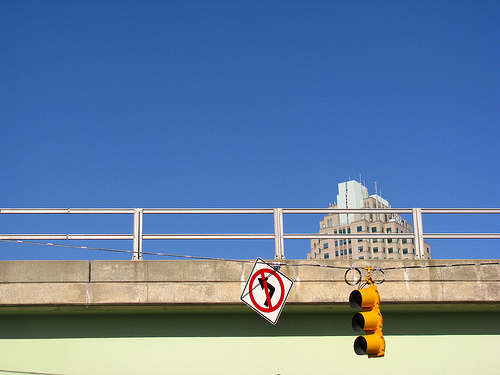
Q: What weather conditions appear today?
A: It is cloudless.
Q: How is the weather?
A: It is cloudless.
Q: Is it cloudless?
A: Yes, it is cloudless.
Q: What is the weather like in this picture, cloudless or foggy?
A: It is cloudless.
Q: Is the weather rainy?
A: No, it is cloudless.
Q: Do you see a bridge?
A: Yes, there is a bridge.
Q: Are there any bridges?
A: Yes, there is a bridge.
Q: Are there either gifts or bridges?
A: Yes, there is a bridge.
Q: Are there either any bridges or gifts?
A: Yes, there is a bridge.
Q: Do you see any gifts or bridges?
A: Yes, there is a bridge.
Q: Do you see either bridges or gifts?
A: Yes, there is a bridge.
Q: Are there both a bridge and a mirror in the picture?
A: No, there is a bridge but no mirrors.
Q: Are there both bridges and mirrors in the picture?
A: No, there is a bridge but no mirrors.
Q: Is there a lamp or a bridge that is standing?
A: Yes, the bridge is standing.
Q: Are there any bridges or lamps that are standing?
A: Yes, the bridge is standing.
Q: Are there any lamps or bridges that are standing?
A: Yes, the bridge is standing.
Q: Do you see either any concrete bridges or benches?
A: Yes, there is a concrete bridge.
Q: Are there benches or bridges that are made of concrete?
A: Yes, the bridge is made of concrete.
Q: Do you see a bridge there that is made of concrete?
A: Yes, there is a bridge that is made of concrete.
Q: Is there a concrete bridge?
A: Yes, there is a bridge that is made of concrete.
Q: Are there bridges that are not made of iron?
A: Yes, there is a bridge that is made of cement.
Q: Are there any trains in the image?
A: No, there are no trains.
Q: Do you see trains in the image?
A: No, there are no trains.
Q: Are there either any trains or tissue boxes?
A: No, there are no trains or tissue boxes.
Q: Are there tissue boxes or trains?
A: No, there are no trains or tissue boxes.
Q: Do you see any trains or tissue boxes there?
A: No, there are no trains or tissue boxes.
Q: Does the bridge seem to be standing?
A: Yes, the bridge is standing.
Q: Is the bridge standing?
A: Yes, the bridge is standing.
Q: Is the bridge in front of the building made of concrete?
A: Yes, the bridge is made of concrete.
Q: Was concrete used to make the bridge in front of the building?
A: Yes, the bridge is made of concrete.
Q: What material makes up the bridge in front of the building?
A: The bridge is made of concrete.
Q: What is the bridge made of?
A: The bridge is made of concrete.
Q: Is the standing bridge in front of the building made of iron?
A: No, the bridge is made of cement.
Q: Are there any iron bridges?
A: No, there is a bridge but it is made of cement.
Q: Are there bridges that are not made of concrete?
A: No, there is a bridge but it is made of concrete.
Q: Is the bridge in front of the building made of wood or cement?
A: The bridge is made of cement.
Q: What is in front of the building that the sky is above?
A: The bridge is in front of the building.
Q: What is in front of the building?
A: The bridge is in front of the building.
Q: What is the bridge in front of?
A: The bridge is in front of the building.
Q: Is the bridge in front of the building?
A: Yes, the bridge is in front of the building.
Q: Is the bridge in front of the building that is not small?
A: Yes, the bridge is in front of the building.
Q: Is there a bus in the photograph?
A: No, there are no buses.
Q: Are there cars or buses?
A: No, there are no buses or cars.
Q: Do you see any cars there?
A: No, there are no cars.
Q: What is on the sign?
A: The arrow is on the sign.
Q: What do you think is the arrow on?
A: The arrow is on the sign.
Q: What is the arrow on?
A: The arrow is on the sign.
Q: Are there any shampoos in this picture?
A: No, there are no shampoos.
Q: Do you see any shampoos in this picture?
A: No, there are no shampoos.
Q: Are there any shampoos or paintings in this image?
A: No, there are no shampoos or paintings.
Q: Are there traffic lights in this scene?
A: Yes, there is a traffic light.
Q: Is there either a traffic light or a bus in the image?
A: Yes, there is a traffic light.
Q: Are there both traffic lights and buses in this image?
A: No, there is a traffic light but no buses.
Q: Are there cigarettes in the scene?
A: No, there are no cigarettes.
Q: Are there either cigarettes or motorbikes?
A: No, there are no cigarettes or motorbikes.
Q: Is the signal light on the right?
A: Yes, the signal light is on the right of the image.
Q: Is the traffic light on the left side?
A: No, the traffic light is on the right of the image.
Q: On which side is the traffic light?
A: The traffic light is on the right of the image.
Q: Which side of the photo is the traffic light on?
A: The traffic light is on the right of the image.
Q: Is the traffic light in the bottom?
A: Yes, the traffic light is in the bottom of the image.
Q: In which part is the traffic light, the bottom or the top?
A: The traffic light is in the bottom of the image.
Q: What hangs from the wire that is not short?
A: The traffic light hangs from the wire.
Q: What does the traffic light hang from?
A: The signal light hangs from the wire.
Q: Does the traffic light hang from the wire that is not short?
A: Yes, the traffic light hangs from the wire.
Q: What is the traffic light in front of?
A: The traffic light is in front of the wire.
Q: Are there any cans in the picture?
A: No, there are no cans.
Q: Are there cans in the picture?
A: No, there are no cans.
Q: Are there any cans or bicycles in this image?
A: No, there are no cans or bicycles.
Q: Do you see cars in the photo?
A: No, there are no cars.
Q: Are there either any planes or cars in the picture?
A: No, there are no cars or planes.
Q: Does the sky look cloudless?
A: Yes, the sky is cloudless.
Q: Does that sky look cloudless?
A: Yes, the sky is cloudless.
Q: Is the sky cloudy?
A: No, the sky is cloudless.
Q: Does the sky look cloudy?
A: No, the sky is cloudless.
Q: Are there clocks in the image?
A: No, there are no clocks.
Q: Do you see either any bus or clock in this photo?
A: No, there are no clocks or buses.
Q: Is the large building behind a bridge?
A: Yes, the building is behind a bridge.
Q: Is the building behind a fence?
A: No, the building is behind a bridge.